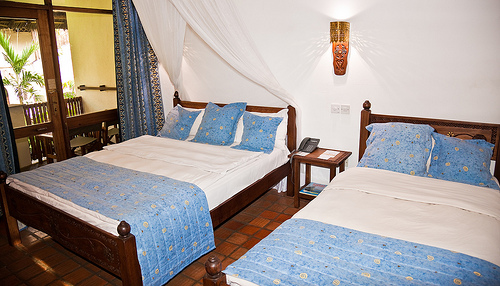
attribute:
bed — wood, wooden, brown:
[0, 91, 299, 284]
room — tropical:
[0, 2, 498, 285]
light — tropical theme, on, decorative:
[329, 20, 349, 75]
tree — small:
[2, 33, 44, 103]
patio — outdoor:
[11, 97, 118, 169]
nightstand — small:
[288, 142, 353, 208]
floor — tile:
[1, 188, 308, 285]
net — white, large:
[130, 1, 301, 193]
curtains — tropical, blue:
[1, 0, 166, 176]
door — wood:
[1, 8, 68, 170]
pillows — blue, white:
[358, 119, 500, 191]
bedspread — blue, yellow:
[8, 156, 216, 284]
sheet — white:
[4, 134, 290, 234]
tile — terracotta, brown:
[0, 187, 309, 285]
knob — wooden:
[117, 220, 132, 235]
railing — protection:
[24, 94, 84, 163]